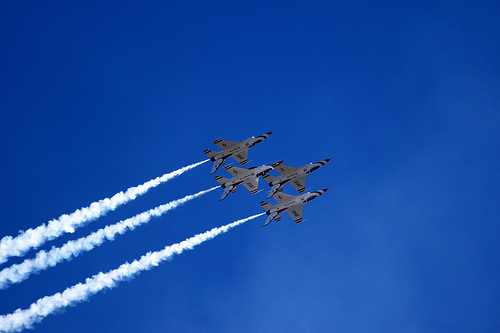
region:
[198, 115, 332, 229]
planes in formation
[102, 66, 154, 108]
blue sky with no clouds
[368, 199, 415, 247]
blue sky with no clouds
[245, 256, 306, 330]
blue sky with no clouds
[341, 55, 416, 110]
blue sky with no clouds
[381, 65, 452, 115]
blue sky with no clouds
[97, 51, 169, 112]
blue sky with no clouds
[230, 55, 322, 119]
blue sky with no clouds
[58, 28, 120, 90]
blue sky with no clouds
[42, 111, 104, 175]
blue sky with no clouds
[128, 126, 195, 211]
planes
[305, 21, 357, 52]
blue sky with no clouds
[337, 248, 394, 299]
blue sky with no clouds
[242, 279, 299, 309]
blue sky with no clouds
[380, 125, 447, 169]
blue sky with no clouds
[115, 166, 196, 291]
smoke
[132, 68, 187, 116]
blue sky with no clouds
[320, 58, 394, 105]
blue sky with no clouds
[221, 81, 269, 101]
blue sky with no clouds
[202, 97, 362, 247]
planes are close together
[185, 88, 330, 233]
planes are performing acrobatics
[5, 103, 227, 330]
white trails behind planes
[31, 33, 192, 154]
blue and clear sky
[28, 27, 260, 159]
no clouds in sky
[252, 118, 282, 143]
black nose on planes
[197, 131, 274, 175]
black and white tails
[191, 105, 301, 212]
black and white wings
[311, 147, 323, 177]
black stripes on noses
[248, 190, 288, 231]
black stripes on tail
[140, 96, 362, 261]
white planes in formation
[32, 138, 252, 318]
white trails behind plane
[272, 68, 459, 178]
no clouds in sky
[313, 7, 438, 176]
sky is deep blue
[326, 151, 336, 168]
black nose on plane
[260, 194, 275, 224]
black and white tails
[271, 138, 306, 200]
black and white wings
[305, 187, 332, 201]
black stripe on nose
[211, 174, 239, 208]
black stripes on tail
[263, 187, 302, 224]
black stripes on wings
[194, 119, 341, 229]
Four jets in flight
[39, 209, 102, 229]
Vapor trail of jet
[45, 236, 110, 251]
Vapor trail of jet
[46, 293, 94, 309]
Vapor trail of jet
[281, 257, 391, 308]
Nice clear blue sky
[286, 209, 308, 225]
Wing of jet airplane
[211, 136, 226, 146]
Wing of jet plane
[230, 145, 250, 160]
Wing of jet plane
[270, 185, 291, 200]
Wing of jet plane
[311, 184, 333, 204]
Nose of jet plane